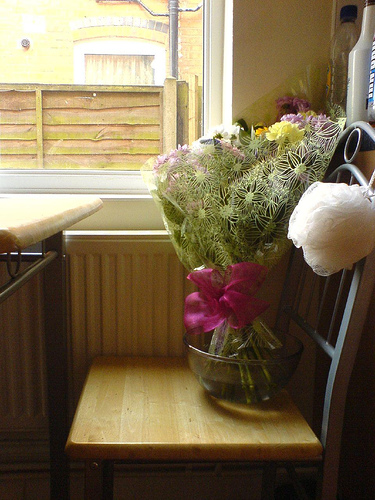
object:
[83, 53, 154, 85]
window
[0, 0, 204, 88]
building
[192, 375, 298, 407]
water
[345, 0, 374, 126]
bottle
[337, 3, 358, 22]
cap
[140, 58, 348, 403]
bouquet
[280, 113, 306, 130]
flower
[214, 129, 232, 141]
flower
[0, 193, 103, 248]
counter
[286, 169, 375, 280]
shower poof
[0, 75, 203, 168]
wall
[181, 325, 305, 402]
glass bowl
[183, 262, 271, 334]
bow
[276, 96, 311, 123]
flower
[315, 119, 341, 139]
flower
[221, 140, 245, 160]
flower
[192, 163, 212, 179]
flower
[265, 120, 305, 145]
flower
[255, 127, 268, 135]
flower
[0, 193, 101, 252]
front table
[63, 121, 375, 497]
chair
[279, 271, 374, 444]
back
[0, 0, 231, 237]
window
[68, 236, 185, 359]
wall